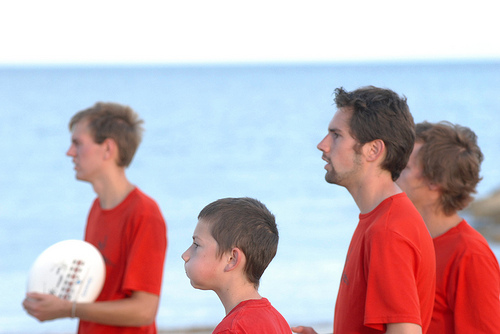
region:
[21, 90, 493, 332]
four male wearing red shirts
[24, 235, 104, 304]
white frisbee with lettering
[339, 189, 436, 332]
red shirt of man with goatee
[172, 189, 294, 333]
young boy in red shirt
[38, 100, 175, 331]
man in background wearing red shirt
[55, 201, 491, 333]
four red short sleeve shirts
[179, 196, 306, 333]
young boy holding his breath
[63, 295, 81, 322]
watch on background man's wrist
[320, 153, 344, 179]
goattee of man with brown hair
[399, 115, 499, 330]
man partially obscured by guy with goatee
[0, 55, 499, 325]
An image of boys, taken outside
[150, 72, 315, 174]
There is water in the background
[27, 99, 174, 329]
Male to the far right holding a frisbee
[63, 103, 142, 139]
Male to far right has sandy colored hair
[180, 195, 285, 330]
small boy on right makes a face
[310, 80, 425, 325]
Man to the left of boy is looking forward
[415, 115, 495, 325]
No face shown on man far left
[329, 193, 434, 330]
The boy and men are wearing red shirts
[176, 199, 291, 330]
He is smaller than the others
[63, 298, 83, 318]
man far right wears a bracelet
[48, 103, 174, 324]
boy standing with frisbee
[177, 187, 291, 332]
boy standing in group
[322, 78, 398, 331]
boy standing in group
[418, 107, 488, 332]
boy standing in group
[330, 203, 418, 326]
red shirt on boy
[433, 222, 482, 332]
red shirt on boy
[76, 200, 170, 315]
red shirt on boy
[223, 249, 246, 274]
ear of young boy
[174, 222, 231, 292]
side profile of boy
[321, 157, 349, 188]
facial hair on man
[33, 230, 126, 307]
frisbee is white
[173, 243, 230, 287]
boy has his cheek puffed out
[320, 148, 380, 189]
man has a beard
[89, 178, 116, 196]
man's adam's apple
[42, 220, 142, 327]
man is holding a frisbee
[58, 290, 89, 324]
man has a bracelet on his left wrist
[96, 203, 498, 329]
four red t-shirts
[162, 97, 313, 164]
ocean is on the side of the people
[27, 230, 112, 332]
frisbee is round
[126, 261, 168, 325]
t-shirt is short sleeved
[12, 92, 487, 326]
there are 4 males in the picture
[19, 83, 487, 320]
the males are all wearing red shirts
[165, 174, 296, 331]
the boy`s hair is brown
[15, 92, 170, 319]
the boy is holding a frisbee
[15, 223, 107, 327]
the frisbee is white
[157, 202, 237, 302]
the boy is puffing his cheeks out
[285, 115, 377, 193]
the guy has a beard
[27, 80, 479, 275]
the people are looking left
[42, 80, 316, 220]
the water is next to the guys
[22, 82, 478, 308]
the people are at the beach